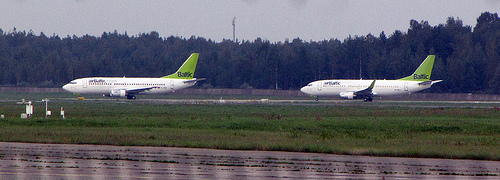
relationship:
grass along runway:
[128, 81, 451, 145] [4, 92, 497, 178]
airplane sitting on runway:
[287, 51, 444, 103] [0, 89, 499, 104]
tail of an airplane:
[408, 49, 440, 79] [301, 55, 443, 104]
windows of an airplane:
[87, 79, 167, 87] [57, 49, 206, 101]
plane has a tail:
[57, 48, 205, 106] [164, 52, 204, 82]